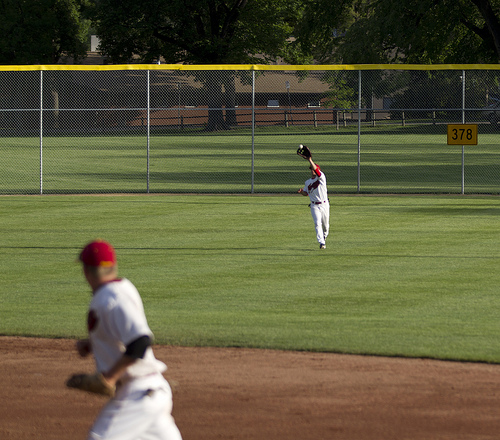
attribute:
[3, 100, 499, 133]
fence — wooden, long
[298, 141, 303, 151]
ball — tiny, white, in air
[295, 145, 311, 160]
glove — black, on hand, brown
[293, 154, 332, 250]
man — wearing glove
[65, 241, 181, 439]
player — running, infielder running, wearing white, wearing red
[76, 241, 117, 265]
cap — red, part of uniform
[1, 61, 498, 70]
yellow — thin, long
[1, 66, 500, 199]
chain link fence — tall, outfield, designating field en, in background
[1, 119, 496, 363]
grass — short, green, striped up, infield, outfield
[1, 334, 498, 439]
dirt — brown, infield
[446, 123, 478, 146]
number sign — yellow, black lettered, feet designation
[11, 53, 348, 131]
building — in background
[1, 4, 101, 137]
tree — green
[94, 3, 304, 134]
tree — green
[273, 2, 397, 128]
tree — leafy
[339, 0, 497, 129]
tree — leafy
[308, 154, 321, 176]
arm — stretched out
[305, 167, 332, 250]
uniform — white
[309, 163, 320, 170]
baseball cap — red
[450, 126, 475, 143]
numbers — black